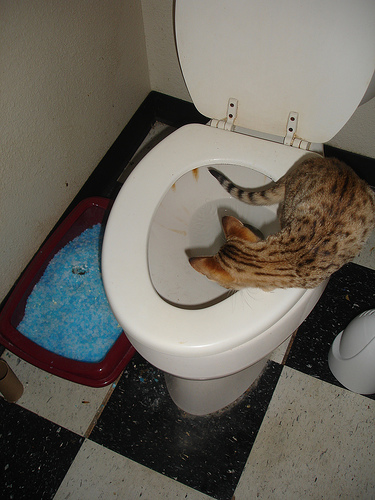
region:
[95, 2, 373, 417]
cat on toilet seat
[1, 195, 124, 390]
red cat box with blue sand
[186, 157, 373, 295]
tan and black cat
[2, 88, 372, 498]
black and white checkered linoleum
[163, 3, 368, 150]
toilet lid is up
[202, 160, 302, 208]
cats tail is in the toilet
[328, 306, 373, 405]
toilet brush is on floor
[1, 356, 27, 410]
empty toilet paper roll on floor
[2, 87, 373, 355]
black molding on the edge of the floor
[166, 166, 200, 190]
rust stain on inside of toilet bowl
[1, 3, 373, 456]
the area has a toilet seat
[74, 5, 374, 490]
the toilet seat is white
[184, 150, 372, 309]
an animal is in the photo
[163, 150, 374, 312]
the animal is a cat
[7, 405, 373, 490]
the floor is tiled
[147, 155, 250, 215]
the toilet is dirty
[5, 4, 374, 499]
the photo was taken indoors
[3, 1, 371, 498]
the photo was taken inside a toilet room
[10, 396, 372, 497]
the tiles are black and white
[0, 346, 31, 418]
the tissue paper has ended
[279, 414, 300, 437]
black spot on white tile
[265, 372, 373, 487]
large white tile on floor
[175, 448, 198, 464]
small white spot on black tile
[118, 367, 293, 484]
black tile wrapped around toilet base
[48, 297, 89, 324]
shiny blue kitty litter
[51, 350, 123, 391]
edge of red bowl holding kitty litter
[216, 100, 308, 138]
black screws in toilet seat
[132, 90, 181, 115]
black edge at end of wall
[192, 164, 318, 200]
cat's tail in toilet bowl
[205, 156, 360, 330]
large brown cat laying on toilet seat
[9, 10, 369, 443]
cat inside of a household bathroom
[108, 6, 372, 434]
cat on top of a toilet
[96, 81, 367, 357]
cat's head inside of a toilet bowl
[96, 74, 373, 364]
beige and dark brown speckled cat on top of a toilet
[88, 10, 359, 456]
white porcelain toilet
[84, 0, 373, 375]
toilet with seat flipped up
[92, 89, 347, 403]
household toilet with rust in the far rear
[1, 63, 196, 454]
blue cat liter inside of burgundy container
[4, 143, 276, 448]
container of cat liter next to a toilet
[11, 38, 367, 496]
creme and black checkerboard tiled bathroom floor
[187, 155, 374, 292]
spotted cat looking in toilet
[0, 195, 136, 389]
litter box under toilet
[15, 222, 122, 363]
blue litter in litter box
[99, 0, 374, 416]
white ceramic toilet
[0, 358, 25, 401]
empty toilet paper roll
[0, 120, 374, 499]
black and white tiled floor under toilet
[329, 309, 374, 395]
white plastic lid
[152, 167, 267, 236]
rust stains in toilet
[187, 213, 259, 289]
cat has two ears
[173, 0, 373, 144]
white toilet lid is open